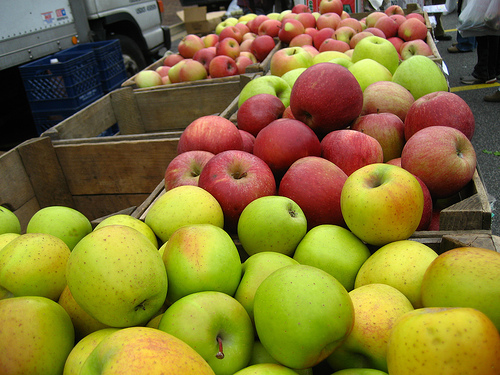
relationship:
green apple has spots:
[252, 262, 357, 369] [265, 273, 342, 334]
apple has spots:
[162, 289, 251, 372] [183, 296, 241, 325]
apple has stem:
[162, 289, 251, 372] [215, 331, 226, 360]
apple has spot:
[0, 0, 500, 375] [208, 170, 217, 182]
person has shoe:
[456, 0, 498, 86] [460, 70, 499, 90]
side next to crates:
[0, 2, 171, 126] [19, 36, 127, 134]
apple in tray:
[0, 0, 500, 375] [130, 111, 484, 222]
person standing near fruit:
[459, 5, 499, 86] [0, 0, 500, 373]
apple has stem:
[0, 0, 500, 375] [215, 332, 225, 359]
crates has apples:
[156, 222, 498, 364] [3, 191, 499, 371]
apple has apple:
[0, 0, 500, 375] [282, 55, 389, 145]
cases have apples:
[11, 14, 485, 362] [76, 14, 427, 351]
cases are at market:
[11, 14, 485, 362] [3, 3, 484, 356]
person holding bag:
[456, 0, 498, 86] [454, 0, 499, 38]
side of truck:
[4, 2, 83, 73] [3, 3, 174, 86]